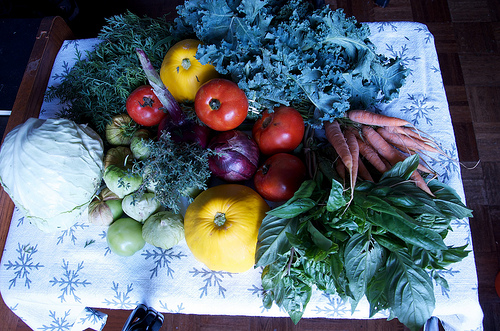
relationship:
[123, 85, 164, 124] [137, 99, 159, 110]
tomato with stem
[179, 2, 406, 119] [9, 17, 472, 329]
kale on platter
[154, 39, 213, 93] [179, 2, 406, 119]
squash and kale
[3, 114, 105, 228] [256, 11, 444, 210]
cabbage and carrots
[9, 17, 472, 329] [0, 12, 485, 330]
platter covering table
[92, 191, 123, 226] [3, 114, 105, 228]
tomato under cabbage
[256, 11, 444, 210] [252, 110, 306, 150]
carrots close to tomato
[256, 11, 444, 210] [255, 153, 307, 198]
carrots close to tomato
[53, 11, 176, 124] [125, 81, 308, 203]
thyme beside tomatoes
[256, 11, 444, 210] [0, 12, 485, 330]
carrots on table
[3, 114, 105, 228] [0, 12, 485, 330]
cabbage on table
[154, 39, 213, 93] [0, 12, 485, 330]
squash on table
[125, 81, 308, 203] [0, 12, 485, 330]
tomatoes on table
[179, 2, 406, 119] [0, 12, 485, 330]
kale on table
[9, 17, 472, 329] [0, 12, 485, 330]
platter on table